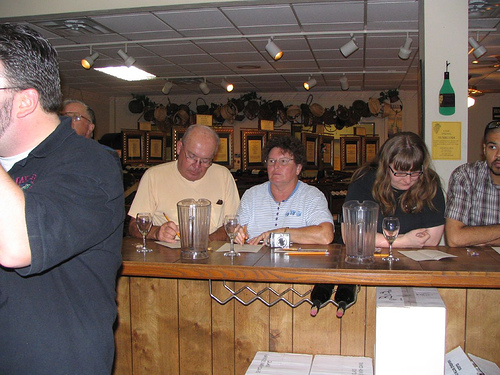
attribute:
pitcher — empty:
[167, 190, 213, 263]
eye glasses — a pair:
[176, 149, 214, 167]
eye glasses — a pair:
[265, 154, 295, 169]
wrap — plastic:
[344, 250, 464, 370]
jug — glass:
[181, 196, 212, 259]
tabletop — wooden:
[250, 251, 326, 274]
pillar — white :
[424, 22, 472, 64]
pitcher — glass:
[176, 198, 211, 258]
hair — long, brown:
[352, 130, 440, 215]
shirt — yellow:
[129, 159, 240, 251]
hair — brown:
[0, 22, 60, 110]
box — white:
[371, 288, 442, 373]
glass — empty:
[220, 216, 241, 250]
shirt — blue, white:
[238, 183, 333, 230]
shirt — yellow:
[129, 161, 239, 240]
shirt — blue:
[5, 117, 125, 361]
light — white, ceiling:
[77, 49, 96, 68]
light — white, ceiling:
[115, 46, 131, 60]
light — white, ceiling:
[265, 37, 283, 57]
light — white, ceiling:
[338, 37, 351, 48]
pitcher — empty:
[176, 199, 204, 272]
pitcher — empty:
[180, 199, 209, 269]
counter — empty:
[129, 242, 479, 287]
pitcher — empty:
[177, 200, 211, 265]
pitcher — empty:
[169, 191, 220, 256]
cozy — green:
[435, 70, 459, 114]